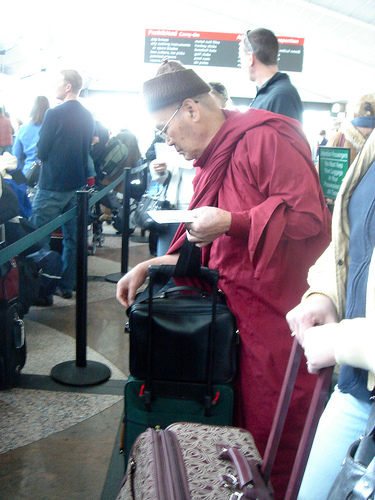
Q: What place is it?
A: It is an airport.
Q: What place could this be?
A: It is an airport.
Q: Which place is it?
A: It is an airport.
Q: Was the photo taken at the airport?
A: Yes, it was taken in the airport.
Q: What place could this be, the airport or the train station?
A: It is the airport.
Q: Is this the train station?
A: No, it is the airport.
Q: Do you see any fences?
A: No, there are no fences.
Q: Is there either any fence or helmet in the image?
A: No, there are no fences or helmets.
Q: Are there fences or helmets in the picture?
A: No, there are no fences or helmets.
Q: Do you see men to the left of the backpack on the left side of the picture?
A: No, the man is to the right of the backpack.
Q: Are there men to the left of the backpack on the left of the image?
A: No, the man is to the right of the backpack.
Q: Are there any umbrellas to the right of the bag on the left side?
A: No, there is a man to the right of the backpack.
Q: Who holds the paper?
A: The man holds the paper.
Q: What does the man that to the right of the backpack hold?
A: The man holds the paper.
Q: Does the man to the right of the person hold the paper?
A: Yes, the man holds the paper.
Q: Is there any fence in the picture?
A: No, there are no fences.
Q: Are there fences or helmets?
A: No, there are no fences or helmets.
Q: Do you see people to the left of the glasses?
A: Yes, there is a person to the left of the glasses.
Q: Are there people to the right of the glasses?
A: No, the person is to the left of the glasses.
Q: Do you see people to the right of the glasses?
A: No, the person is to the left of the glasses.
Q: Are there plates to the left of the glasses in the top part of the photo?
A: No, there is a person to the left of the glasses.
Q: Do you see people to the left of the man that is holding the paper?
A: Yes, there is a person to the left of the man.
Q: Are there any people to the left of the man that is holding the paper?
A: Yes, there is a person to the left of the man.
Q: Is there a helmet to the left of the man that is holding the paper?
A: No, there is a person to the left of the man.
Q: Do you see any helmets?
A: No, there are no helmets.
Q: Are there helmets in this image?
A: No, there are no helmets.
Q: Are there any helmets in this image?
A: No, there are no helmets.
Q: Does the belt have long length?
A: Yes, the belt is long.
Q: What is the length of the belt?
A: The belt is long.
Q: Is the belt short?
A: No, the belt is long.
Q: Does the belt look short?
A: No, the belt is long.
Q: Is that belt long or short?
A: The belt is long.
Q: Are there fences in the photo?
A: No, there are no fences.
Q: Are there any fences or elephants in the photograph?
A: No, there are no fences or elephants.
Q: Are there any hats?
A: Yes, there is a hat.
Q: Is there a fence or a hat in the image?
A: Yes, there is a hat.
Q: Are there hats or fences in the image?
A: Yes, there is a hat.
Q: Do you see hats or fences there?
A: Yes, there is a hat.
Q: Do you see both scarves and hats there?
A: No, there is a hat but no scarves.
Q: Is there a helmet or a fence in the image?
A: No, there are no helmets or fences.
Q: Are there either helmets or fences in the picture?
A: No, there are no helmets or fences.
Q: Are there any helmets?
A: No, there are no helmets.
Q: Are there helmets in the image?
A: No, there are no helmets.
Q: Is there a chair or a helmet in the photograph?
A: No, there are no helmets or chairs.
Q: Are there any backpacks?
A: Yes, there is a backpack.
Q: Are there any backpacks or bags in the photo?
A: Yes, there is a backpack.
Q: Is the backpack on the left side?
A: Yes, the backpack is on the left of the image.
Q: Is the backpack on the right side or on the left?
A: The backpack is on the left of the image.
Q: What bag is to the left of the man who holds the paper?
A: The bag is a backpack.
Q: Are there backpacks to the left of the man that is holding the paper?
A: Yes, there is a backpack to the left of the man.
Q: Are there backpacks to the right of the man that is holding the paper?
A: No, the backpack is to the left of the man.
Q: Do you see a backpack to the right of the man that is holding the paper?
A: No, the backpack is to the left of the man.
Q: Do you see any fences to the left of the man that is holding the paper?
A: No, there is a backpack to the left of the man.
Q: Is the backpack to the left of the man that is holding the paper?
A: Yes, the backpack is to the left of the man.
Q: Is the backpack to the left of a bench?
A: No, the backpack is to the left of the man.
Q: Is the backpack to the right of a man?
A: No, the backpack is to the left of a man.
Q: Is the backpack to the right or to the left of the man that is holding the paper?
A: The backpack is to the left of the man.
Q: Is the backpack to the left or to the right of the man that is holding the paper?
A: The backpack is to the left of the man.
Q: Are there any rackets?
A: No, there are no rackets.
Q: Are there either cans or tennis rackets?
A: No, there are no tennis rackets or cans.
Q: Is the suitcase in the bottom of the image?
A: Yes, the suitcase is in the bottom of the image.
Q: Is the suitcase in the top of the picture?
A: No, the suitcase is in the bottom of the image.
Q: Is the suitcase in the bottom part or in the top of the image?
A: The suitcase is in the bottom of the image.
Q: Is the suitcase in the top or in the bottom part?
A: The suitcase is in the bottom of the image.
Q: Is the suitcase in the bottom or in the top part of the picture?
A: The suitcase is in the bottom of the image.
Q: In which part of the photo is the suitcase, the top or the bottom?
A: The suitcase is in the bottom of the image.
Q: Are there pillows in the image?
A: No, there are no pillows.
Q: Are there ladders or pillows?
A: No, there are no pillows or ladders.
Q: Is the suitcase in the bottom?
A: Yes, the suitcase is in the bottom of the image.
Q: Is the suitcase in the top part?
A: No, the suitcase is in the bottom of the image.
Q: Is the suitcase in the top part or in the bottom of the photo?
A: The suitcase is in the bottom of the image.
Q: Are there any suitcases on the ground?
A: Yes, there is a suitcase on the ground.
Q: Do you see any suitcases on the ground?
A: Yes, there is a suitcase on the ground.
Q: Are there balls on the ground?
A: No, there is a suitcase on the ground.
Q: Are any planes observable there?
A: No, there are no planes.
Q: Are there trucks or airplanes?
A: No, there are no airplanes or trucks.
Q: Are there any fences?
A: No, there are no fences.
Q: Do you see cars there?
A: No, there are no cars.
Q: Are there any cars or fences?
A: No, there are no cars or fences.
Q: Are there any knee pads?
A: No, there are no knee pads.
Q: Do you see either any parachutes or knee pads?
A: No, there are no knee pads or parachutes.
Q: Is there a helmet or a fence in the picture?
A: No, there are no helmets or fences.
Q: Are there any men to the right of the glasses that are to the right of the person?
A: Yes, there is a man to the right of the glasses.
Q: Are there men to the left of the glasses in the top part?
A: No, the man is to the right of the glasses.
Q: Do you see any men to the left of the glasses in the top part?
A: No, the man is to the right of the glasses.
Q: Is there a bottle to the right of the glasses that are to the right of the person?
A: No, there is a man to the right of the glasses.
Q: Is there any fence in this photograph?
A: No, there are no fences.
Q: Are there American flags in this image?
A: No, there are no American flags.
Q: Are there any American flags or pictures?
A: No, there are no American flags or pictures.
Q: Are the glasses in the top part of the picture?
A: Yes, the glasses are in the top of the image.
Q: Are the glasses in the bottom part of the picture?
A: No, the glasses are in the top of the image.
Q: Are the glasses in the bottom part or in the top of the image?
A: The glasses are in the top of the image.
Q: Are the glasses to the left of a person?
A: No, the glasses are to the right of a person.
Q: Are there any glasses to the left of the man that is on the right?
A: Yes, there are glasses to the left of the man.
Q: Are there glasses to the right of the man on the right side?
A: No, the glasses are to the left of the man.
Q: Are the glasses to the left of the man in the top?
A: Yes, the glasses are to the left of the man.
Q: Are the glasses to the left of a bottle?
A: No, the glasses are to the left of the man.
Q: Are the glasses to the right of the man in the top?
A: No, the glasses are to the left of the man.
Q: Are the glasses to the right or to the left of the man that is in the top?
A: The glasses are to the left of the man.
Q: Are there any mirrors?
A: No, there are no mirrors.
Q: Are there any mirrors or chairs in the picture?
A: No, there are no mirrors or chairs.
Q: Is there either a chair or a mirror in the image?
A: No, there are no mirrors or chairs.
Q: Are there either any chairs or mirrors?
A: No, there are no mirrors or chairs.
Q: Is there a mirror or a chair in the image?
A: No, there are no mirrors or chairs.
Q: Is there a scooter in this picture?
A: No, there are no scooters.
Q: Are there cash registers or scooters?
A: No, there are no scooters or cash registers.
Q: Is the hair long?
A: Yes, the hair is long.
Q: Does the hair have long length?
A: Yes, the hair is long.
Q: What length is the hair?
A: The hair is long.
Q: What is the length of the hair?
A: The hair is long.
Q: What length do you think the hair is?
A: The hair is long.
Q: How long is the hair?
A: The hair is long.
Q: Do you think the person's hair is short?
A: No, the hair is long.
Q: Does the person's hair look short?
A: No, the hair is long.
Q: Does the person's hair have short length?
A: No, the hair is long.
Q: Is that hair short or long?
A: The hair is long.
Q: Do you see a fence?
A: No, there are no fences.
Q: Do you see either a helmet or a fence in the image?
A: No, there are no fences or helmets.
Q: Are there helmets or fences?
A: No, there are no fences or helmets.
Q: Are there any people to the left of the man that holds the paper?
A: Yes, there is a person to the left of the man.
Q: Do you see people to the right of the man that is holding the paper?
A: No, the person is to the left of the man.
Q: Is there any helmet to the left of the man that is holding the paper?
A: No, there is a person to the left of the man.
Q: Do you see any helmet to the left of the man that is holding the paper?
A: No, there is a person to the left of the man.